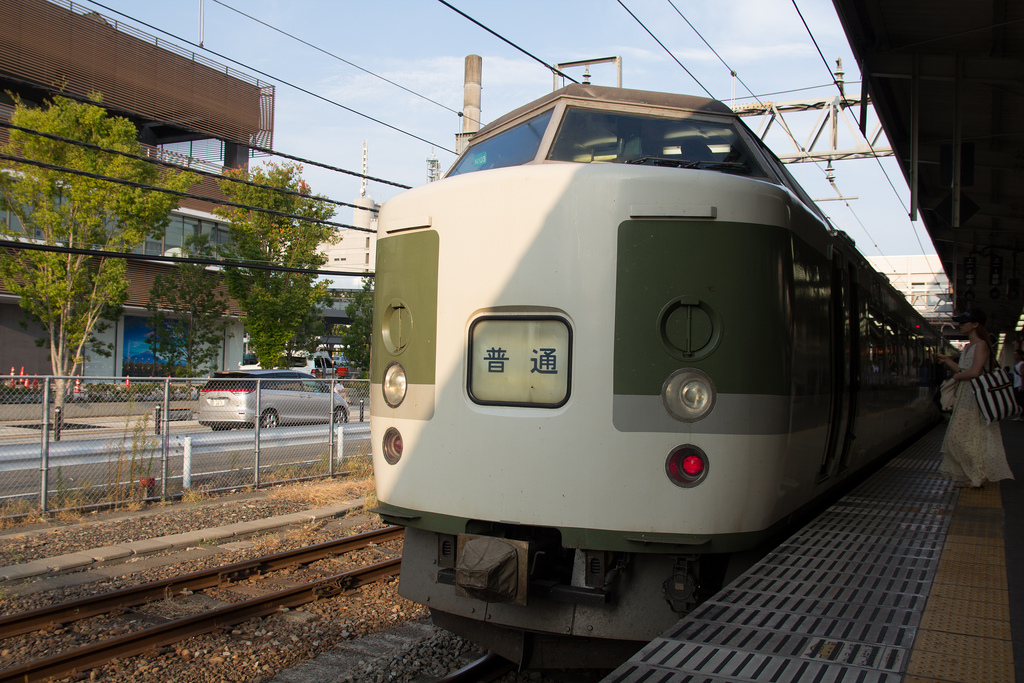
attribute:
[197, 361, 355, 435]
van — gold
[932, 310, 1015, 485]
woman — trendy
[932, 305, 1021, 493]
woman — trendy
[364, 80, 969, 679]
train — tan, green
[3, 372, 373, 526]
fence — chain linked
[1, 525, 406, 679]
train track — empty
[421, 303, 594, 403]
letters — chinese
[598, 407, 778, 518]
light — red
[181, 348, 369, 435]
car — brown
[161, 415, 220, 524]
pole — gray